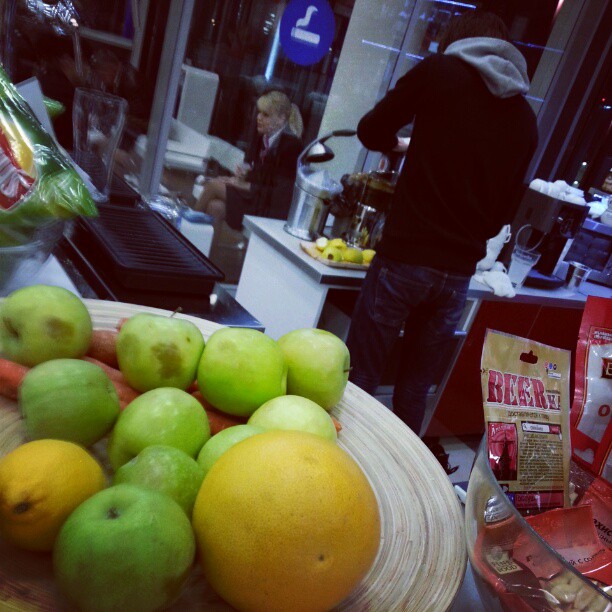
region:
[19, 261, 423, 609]
a group of fruit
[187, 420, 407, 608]
this is a grapefruit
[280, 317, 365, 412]
a green apple on the side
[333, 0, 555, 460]
a man standing up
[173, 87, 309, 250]
a woman sitting down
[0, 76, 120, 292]
corner of a bag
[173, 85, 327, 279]
woman has legs crossed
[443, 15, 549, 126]
hood on the jacket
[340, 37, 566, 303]
person wearing a black jacket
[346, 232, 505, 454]
person wearing blue jeans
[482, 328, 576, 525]
A bag has beer written on it.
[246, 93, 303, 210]
A person in a dark shirt has blonde hair.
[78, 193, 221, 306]
A black tray has slots on it.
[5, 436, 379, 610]
Two pieces of fruit are yellow.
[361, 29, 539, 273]
A man is wearing a black and gray hoodie.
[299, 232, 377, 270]
Yellow apples are on a tray.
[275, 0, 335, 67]
A blue circle has a underlined S on it.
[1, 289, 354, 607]
Ten green apples are on the plate.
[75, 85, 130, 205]
An empty glass is by a green bag edge sticking out.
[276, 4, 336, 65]
Round blue sign on glass.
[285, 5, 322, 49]
White cigarette and smoke drawing.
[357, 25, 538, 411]
A person wearing a black shirt.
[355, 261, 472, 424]
Blue jeans being worn by a person.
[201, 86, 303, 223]
Blonde woman sitting down.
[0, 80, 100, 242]
Green bag of potato chips.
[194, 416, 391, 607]
Large grapefruit in fruit bowl.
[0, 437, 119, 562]
Lemon in a fruit bowl.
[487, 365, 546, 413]
The word 'beer' in red.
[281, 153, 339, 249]
Silver container on counter behind tray of fruit.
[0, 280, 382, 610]
plate of mixed fruits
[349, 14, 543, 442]
man wearing black jacket with grey hood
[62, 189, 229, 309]
empty small black grill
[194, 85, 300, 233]
woman sitting in a waiting room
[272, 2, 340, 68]
round blue sign with white design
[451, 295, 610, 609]
bowl full of beef jerky packages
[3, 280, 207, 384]
pair of bruised green apples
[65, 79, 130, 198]
empty beer glass on counter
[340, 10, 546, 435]
man wearing dark blue skinny jeans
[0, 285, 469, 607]
a round dish with swirl design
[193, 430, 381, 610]
a ripened orange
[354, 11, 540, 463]
Man in blue jeans with a gray hood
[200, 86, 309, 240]
a woman in a business suit and blonde hair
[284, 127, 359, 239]
a stainless steel fruit juicer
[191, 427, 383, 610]
large yellow grapefruit on plate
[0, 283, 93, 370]
green apple with brown bruise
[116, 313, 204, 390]
green apple with brown bruise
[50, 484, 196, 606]
green apple with brown bruise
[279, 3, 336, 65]
round blue sign with white no smoking insignia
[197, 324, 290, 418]
green apple sitting on a plate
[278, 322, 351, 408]
green apple sitting on a plate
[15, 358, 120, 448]
green apple sitting on a plate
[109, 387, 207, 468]
green apple sitting on a plate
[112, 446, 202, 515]
green apple sitting on a plate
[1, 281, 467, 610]
plate with assorted green and yellow fruit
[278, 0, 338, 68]
round blue and white smoking sign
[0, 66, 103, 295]
blurry bags of chips in clear bowl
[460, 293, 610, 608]
bags of snack foods in clear bowl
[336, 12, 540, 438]
man in jeans and black jacket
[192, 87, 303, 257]
blonde woman sitting wearing skirt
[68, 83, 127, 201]
tall clear glass